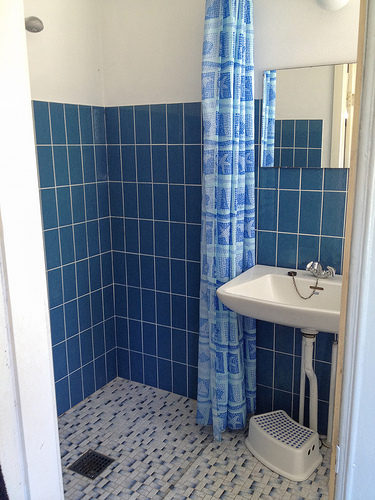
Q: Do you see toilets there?
A: No, there are no toilets.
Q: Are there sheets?
A: No, there are no sheets.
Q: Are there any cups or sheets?
A: No, there are no sheets or cups.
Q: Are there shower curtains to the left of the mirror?
A: Yes, there is a shower curtain to the left of the mirror.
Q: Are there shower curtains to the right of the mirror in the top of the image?
A: No, the shower curtain is to the left of the mirror.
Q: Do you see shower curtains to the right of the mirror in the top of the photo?
A: No, the shower curtain is to the left of the mirror.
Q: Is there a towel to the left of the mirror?
A: No, there is a shower curtain to the left of the mirror.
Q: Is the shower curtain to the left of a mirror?
A: Yes, the shower curtain is to the left of a mirror.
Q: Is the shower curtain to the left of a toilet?
A: No, the shower curtain is to the left of a mirror.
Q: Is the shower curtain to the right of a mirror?
A: No, the shower curtain is to the left of a mirror.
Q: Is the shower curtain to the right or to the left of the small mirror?
A: The shower curtain is to the left of the mirror.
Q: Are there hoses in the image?
A: No, there are no hoses.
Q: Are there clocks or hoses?
A: No, there are no hoses or clocks.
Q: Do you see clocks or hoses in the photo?
A: No, there are no hoses or clocks.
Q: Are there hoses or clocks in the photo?
A: No, there are no hoses or clocks.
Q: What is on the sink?
A: The chain is on the sink.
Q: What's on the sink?
A: The chain is on the sink.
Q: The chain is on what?
A: The chain is on the sink.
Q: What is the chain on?
A: The chain is on the sink.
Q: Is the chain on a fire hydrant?
A: No, the chain is on the sink.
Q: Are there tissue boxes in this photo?
A: No, there are no tissue boxes.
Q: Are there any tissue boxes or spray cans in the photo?
A: No, there are no tissue boxes or spray cans.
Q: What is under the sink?
A: The pipes are under the sink.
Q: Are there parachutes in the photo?
A: No, there are no parachutes.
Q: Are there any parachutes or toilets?
A: No, there are no parachutes or toilets.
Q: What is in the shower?
A: The drain is in the shower.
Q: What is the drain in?
A: The drain is in the shower.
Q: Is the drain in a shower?
A: Yes, the drain is in a shower.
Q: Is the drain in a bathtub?
A: No, the drain is in a shower.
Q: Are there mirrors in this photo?
A: Yes, there is a mirror.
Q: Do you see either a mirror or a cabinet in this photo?
A: Yes, there is a mirror.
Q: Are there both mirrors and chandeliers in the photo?
A: No, there is a mirror but no chandeliers.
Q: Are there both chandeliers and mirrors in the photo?
A: No, there is a mirror but no chandeliers.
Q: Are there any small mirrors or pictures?
A: Yes, there is a small mirror.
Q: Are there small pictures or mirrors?
A: Yes, there is a small mirror.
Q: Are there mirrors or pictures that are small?
A: Yes, the mirror is small.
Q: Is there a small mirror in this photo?
A: Yes, there is a small mirror.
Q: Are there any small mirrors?
A: Yes, there is a small mirror.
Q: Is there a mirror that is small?
A: Yes, there is a mirror that is small.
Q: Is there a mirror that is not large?
A: Yes, there is a small mirror.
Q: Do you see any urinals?
A: No, there are no urinals.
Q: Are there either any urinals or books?
A: No, there are no urinals or books.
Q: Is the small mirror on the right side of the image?
A: Yes, the mirror is on the right of the image.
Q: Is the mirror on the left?
A: No, the mirror is on the right of the image.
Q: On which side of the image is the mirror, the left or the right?
A: The mirror is on the right of the image.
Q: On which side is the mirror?
A: The mirror is on the right of the image.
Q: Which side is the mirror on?
A: The mirror is on the right of the image.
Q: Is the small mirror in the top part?
A: Yes, the mirror is in the top of the image.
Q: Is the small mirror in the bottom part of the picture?
A: No, the mirror is in the top of the image.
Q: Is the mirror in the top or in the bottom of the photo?
A: The mirror is in the top of the image.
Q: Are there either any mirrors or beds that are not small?
A: No, there is a mirror but it is small.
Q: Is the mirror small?
A: Yes, the mirror is small.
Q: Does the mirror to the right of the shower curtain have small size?
A: Yes, the mirror is small.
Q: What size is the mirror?
A: The mirror is small.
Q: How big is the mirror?
A: The mirror is small.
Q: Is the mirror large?
A: No, the mirror is small.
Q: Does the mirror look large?
A: No, the mirror is small.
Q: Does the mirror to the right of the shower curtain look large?
A: No, the mirror is small.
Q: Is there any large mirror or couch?
A: No, there is a mirror but it is small.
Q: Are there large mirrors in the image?
A: No, there is a mirror but it is small.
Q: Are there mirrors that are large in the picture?
A: No, there is a mirror but it is small.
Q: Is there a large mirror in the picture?
A: No, there is a mirror but it is small.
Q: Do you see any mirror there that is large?
A: No, there is a mirror but it is small.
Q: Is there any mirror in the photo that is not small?
A: No, there is a mirror but it is small.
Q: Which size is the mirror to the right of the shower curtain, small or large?
A: The mirror is small.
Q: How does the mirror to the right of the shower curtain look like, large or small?
A: The mirror is small.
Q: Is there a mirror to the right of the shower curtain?
A: Yes, there is a mirror to the right of the shower curtain.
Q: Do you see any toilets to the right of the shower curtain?
A: No, there is a mirror to the right of the shower curtain.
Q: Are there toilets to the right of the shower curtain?
A: No, there is a mirror to the right of the shower curtain.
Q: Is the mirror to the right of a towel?
A: No, the mirror is to the right of the shower curtain.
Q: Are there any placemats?
A: No, there are no placemats.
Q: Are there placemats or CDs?
A: No, there are no placemats or cds.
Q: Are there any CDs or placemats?
A: No, there are no placemats or cds.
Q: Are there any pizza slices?
A: No, there are no pizza slices.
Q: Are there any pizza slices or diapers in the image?
A: No, there are no pizza slices or diapers.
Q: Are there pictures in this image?
A: No, there are no pictures.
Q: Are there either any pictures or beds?
A: No, there are no pictures or beds.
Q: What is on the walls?
A: The tiles are on the walls.